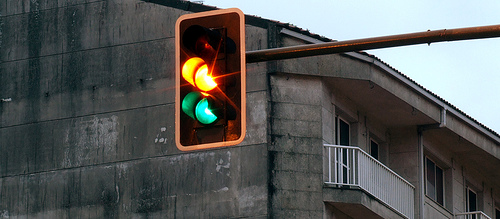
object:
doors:
[335, 116, 358, 185]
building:
[0, 0, 499, 219]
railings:
[320, 143, 414, 219]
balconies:
[320, 143, 458, 219]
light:
[194, 63, 219, 95]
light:
[193, 99, 219, 124]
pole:
[243, 22, 498, 62]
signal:
[174, 7, 247, 151]